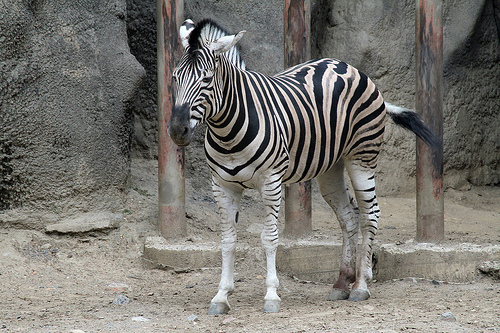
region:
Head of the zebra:
[164, 18, 244, 148]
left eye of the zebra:
[200, 72, 216, 84]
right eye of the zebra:
[167, 72, 179, 84]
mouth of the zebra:
[165, 127, 197, 154]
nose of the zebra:
[167, 122, 191, 137]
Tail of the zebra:
[382, 100, 439, 150]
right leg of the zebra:
[202, 183, 242, 315]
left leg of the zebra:
[253, 178, 285, 314]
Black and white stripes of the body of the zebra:
[272, 77, 348, 163]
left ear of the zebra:
[214, 28, 246, 54]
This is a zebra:
[160, 13, 449, 330]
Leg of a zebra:
[345, 154, 388, 319]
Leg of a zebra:
[317, 164, 365, 321]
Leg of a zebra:
[252, 167, 324, 322]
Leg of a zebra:
[200, 162, 250, 327]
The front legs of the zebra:
[210, 180, 283, 314]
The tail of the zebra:
[382, 105, 438, 153]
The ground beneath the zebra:
[0, 269, 498, 331]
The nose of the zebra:
[169, 123, 191, 138]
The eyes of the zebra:
[171, 73, 214, 85]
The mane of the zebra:
[190, 17, 242, 51]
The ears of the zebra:
[181, 22, 243, 50]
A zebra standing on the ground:
[168, 23, 440, 315]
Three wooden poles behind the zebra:
[156, 2, 446, 240]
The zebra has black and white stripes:
[169, 17, 434, 313]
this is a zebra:
[169, 18, 443, 320]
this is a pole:
[147, 0, 217, 240]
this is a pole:
[270, 2, 326, 219]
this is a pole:
[410, 7, 460, 242]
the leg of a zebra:
[334, 155, 396, 300]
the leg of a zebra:
[311, 178, 369, 310]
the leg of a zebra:
[250, 184, 297, 322]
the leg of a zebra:
[193, 177, 252, 331]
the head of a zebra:
[164, 17, 232, 144]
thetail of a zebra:
[376, 60, 443, 190]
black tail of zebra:
[374, 94, 469, 170]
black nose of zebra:
[162, 97, 197, 155]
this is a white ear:
[209, 32, 259, 61]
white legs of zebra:
[195, 239, 300, 316]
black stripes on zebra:
[229, 78, 319, 153]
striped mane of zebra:
[178, 15, 231, 59]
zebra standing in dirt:
[80, 10, 468, 330]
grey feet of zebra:
[197, 285, 380, 330]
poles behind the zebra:
[108, 2, 479, 264]